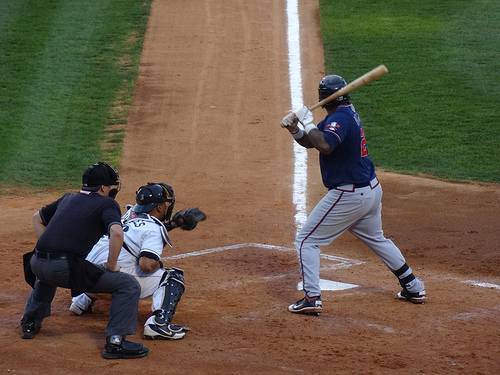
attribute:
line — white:
[274, 2, 321, 246]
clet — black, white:
[278, 297, 332, 322]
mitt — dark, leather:
[170, 202, 212, 237]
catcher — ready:
[18, 158, 208, 363]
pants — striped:
[292, 175, 426, 296]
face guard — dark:
[75, 161, 122, 200]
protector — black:
[154, 263, 199, 333]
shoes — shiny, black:
[102, 339, 147, 360]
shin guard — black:
[160, 264, 182, 324]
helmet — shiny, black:
[316, 73, 351, 105]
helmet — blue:
[313, 54, 374, 129]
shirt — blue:
[318, 104, 374, 191]